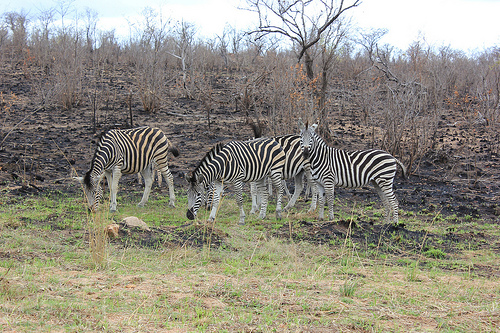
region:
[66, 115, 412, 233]
four zebras in a field eating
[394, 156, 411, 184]
the tail of a zebra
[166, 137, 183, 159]
the tail of a zebra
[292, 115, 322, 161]
a head of a zebra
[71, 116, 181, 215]
a zebra eating grass in a field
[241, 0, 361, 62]
the branches of a tree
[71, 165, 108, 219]
the head of a zebra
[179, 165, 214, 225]
the head of a zebra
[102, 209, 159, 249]
a rock in a field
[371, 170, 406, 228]
the hind leg of a zebra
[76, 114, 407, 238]
zebras in a field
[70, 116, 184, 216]
a zebra eating the grass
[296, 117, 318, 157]
the face of a zebra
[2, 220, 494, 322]
the grass in front of the zebras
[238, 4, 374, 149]
a tree in the background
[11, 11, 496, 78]
the tops of many trees in the background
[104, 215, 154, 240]
some rocks on a pile of dirt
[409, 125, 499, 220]
mud in the background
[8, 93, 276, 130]
a fence in the background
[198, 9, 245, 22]
a cloud in the sky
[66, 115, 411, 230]
four zebras standing together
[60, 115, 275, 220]
two zebras grazing from the grass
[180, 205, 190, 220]
black nose of zebra grazing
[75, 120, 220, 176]
black and white manes on the zebras necks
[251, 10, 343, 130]
tree behind the four zebras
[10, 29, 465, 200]
dead brush and grass behind the zebras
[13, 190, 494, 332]
grass the zebras are grazing from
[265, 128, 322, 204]
zebra obscured by the other zebras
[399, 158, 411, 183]
black and white tail of zebra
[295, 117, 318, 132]
ears of the zebra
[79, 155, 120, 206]
the head of a zebra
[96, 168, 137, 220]
the front legs of a zebra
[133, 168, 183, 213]
the back legs of a zebra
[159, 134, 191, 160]
the tail of a zebra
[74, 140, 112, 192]
the main of a zebra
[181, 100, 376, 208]
the strips of a zebra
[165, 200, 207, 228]
the nose of a zebra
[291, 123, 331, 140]
the ears of a zebra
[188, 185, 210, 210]
the eye of a zebra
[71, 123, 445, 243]
zebras standing in a field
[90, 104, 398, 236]
three zebras on grass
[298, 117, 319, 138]
zebra has white ears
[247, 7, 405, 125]
bare tree behind zebras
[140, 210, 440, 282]
brown dirt on ground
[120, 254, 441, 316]
grass is green and brown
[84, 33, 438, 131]
bare trees on hill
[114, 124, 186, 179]
black and white stripes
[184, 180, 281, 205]
zebras have white legs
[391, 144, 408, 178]
black and white tail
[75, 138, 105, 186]
black and white mane